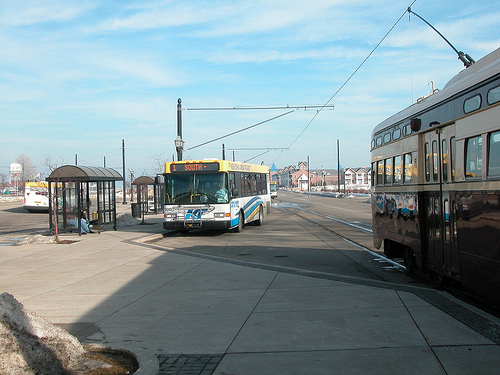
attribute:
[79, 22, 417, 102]
clouds — white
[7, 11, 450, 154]
sky — blue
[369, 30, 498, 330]
rail car — old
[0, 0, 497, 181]
clouds — white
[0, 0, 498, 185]
sky — blue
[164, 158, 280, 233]
bus — bold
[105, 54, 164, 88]
clouds — white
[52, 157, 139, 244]
bus stop — black, large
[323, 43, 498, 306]
car — cable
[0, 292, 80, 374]
snow — brown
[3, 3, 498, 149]
clouds — white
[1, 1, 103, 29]
clouds — white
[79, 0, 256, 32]
clouds — white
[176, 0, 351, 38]
clouds — white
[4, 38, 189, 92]
clouds — white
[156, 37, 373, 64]
clouds — white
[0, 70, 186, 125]
clouds — white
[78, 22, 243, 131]
sky — blue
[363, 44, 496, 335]
trolley — electric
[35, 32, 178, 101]
clouds — white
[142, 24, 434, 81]
sky — blue